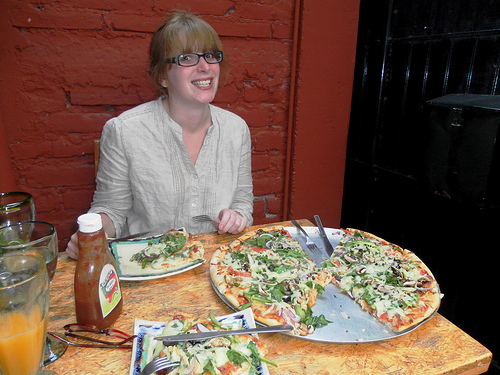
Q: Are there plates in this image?
A: Yes, there is a plate.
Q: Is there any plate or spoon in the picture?
A: Yes, there is a plate.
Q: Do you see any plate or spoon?
A: Yes, there is a plate.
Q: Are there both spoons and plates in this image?
A: No, there is a plate but no spoons.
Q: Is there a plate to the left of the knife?
A: Yes, there is a plate to the left of the knife.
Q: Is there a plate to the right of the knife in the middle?
A: No, the plate is to the left of the knife.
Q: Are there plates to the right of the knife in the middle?
A: No, the plate is to the left of the knife.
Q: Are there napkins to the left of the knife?
A: No, there is a plate to the left of the knife.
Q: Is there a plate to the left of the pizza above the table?
A: Yes, there is a plate to the left of the pizza.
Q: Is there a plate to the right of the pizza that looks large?
A: No, the plate is to the left of the pizza.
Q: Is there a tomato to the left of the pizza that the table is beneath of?
A: No, there is a plate to the left of the pizza.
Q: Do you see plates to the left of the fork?
A: Yes, there is a plate to the left of the fork.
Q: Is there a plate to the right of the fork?
A: No, the plate is to the left of the fork.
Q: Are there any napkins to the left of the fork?
A: No, there is a plate to the left of the fork.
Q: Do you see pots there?
A: No, there are no pots.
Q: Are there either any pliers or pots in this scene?
A: No, there are no pots or pliers.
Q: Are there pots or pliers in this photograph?
A: No, there are no pots or pliers.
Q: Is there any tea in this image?
A: No, there is no tea.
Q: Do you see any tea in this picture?
A: No, there is no tea.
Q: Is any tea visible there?
A: No, there is no tea.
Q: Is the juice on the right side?
A: No, the juice is on the left of the image.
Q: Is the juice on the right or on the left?
A: The juice is on the left of the image.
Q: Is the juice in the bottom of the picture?
A: Yes, the juice is in the bottom of the image.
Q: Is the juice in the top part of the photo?
A: No, the juice is in the bottom of the image.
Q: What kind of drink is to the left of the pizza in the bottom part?
A: The drink is juice.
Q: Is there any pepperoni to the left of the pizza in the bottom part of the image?
A: No, there is juice to the left of the pizza.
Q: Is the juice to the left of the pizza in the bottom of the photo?
A: Yes, the juice is to the left of the pizza.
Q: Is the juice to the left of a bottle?
A: No, the juice is to the left of the pizza.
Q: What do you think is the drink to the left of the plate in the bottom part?
A: The drink is juice.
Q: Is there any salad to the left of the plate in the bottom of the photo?
A: No, there is juice to the left of the plate.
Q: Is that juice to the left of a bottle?
A: No, the juice is to the left of a plate.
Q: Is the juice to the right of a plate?
A: No, the juice is to the left of a plate.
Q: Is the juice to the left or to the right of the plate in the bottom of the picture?
A: The juice is to the left of the plate.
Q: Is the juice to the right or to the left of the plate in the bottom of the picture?
A: The juice is to the left of the plate.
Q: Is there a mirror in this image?
A: No, there are no mirrors.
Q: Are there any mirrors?
A: No, there are no mirrors.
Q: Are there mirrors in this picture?
A: No, there are no mirrors.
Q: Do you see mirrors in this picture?
A: No, there are no mirrors.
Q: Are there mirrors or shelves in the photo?
A: No, there are no mirrors or shelves.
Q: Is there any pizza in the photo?
A: Yes, there is a pizza.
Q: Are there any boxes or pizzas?
A: Yes, there is a pizza.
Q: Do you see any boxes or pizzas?
A: Yes, there is a pizza.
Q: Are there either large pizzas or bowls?
A: Yes, there is a large pizza.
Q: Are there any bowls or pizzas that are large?
A: Yes, the pizza is large.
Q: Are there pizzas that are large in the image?
A: Yes, there is a large pizza.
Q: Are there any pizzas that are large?
A: Yes, there is a pizza that is large.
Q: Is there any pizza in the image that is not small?
A: Yes, there is a large pizza.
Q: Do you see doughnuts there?
A: No, there are no doughnuts.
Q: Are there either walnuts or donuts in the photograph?
A: No, there are no donuts or walnuts.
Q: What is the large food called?
A: The food is a pizza.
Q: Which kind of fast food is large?
A: The fast food is a pizza.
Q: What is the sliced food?
A: The food is a pizza.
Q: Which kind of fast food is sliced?
A: The fast food is a pizza.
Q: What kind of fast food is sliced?
A: The fast food is a pizza.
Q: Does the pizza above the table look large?
A: Yes, the pizza is large.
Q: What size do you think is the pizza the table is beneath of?
A: The pizza is large.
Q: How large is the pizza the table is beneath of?
A: The pizza is large.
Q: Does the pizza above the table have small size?
A: No, the pizza is large.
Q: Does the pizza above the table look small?
A: No, the pizza is large.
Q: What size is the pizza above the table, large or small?
A: The pizza is large.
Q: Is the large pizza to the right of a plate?
A: Yes, the pizza is to the right of a plate.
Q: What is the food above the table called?
A: The food is a pizza.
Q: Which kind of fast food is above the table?
A: The food is a pizza.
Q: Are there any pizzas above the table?
A: Yes, there is a pizza above the table.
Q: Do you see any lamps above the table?
A: No, there is a pizza above the table.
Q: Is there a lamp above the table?
A: No, there is a pizza above the table.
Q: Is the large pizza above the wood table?
A: Yes, the pizza is above the table.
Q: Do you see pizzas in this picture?
A: Yes, there is a pizza.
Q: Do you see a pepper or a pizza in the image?
A: Yes, there is a pizza.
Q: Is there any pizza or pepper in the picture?
A: Yes, there is a pizza.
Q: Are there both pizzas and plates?
A: Yes, there are both a pizza and a plate.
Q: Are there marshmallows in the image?
A: No, there are no marshmallows.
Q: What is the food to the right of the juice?
A: The food is a pizza.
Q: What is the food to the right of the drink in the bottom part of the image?
A: The food is a pizza.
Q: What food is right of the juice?
A: The food is a pizza.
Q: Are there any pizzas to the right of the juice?
A: Yes, there is a pizza to the right of the juice.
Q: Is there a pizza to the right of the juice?
A: Yes, there is a pizza to the right of the juice.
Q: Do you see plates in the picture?
A: Yes, there is a plate.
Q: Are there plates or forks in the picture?
A: Yes, there is a plate.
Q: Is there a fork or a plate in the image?
A: Yes, there is a plate.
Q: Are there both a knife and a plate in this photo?
A: Yes, there are both a plate and a knife.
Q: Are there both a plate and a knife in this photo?
A: Yes, there are both a plate and a knife.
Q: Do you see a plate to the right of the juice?
A: Yes, there is a plate to the right of the juice.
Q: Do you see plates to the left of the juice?
A: No, the plate is to the right of the juice.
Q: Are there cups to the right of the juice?
A: No, there is a plate to the right of the juice.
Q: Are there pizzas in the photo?
A: Yes, there is a pizza.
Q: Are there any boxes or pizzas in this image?
A: Yes, there is a pizza.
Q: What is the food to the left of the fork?
A: The food is a pizza.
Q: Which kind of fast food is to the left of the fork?
A: The food is a pizza.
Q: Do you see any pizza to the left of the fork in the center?
A: Yes, there is a pizza to the left of the fork.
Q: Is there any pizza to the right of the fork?
A: No, the pizza is to the left of the fork.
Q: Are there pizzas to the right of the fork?
A: No, the pizza is to the left of the fork.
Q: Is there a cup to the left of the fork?
A: No, there is a pizza to the left of the fork.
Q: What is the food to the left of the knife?
A: The food is a pizza.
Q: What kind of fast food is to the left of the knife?
A: The food is a pizza.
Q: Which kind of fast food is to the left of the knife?
A: The food is a pizza.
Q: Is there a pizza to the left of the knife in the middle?
A: Yes, there is a pizza to the left of the knife.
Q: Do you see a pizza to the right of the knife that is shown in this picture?
A: No, the pizza is to the left of the knife.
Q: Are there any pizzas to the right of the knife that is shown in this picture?
A: No, the pizza is to the left of the knife.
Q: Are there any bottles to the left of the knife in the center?
A: No, there is a pizza to the left of the knife.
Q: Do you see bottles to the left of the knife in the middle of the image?
A: No, there is a pizza to the left of the knife.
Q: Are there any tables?
A: Yes, there is a table.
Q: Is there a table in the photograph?
A: Yes, there is a table.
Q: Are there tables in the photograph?
A: Yes, there is a table.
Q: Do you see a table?
A: Yes, there is a table.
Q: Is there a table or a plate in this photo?
A: Yes, there is a table.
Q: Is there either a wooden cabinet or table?
A: Yes, there is a wood table.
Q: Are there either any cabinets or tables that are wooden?
A: Yes, the table is wooden.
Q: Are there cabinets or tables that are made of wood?
A: Yes, the table is made of wood.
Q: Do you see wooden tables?
A: Yes, there is a wood table.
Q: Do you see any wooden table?
A: Yes, there is a wood table.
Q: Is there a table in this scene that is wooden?
A: Yes, there is a table that is wooden.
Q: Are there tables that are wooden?
A: Yes, there is a table that is wooden.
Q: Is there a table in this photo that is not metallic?
A: Yes, there is a wooden table.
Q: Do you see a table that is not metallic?
A: Yes, there is a wooden table.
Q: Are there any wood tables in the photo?
A: Yes, there is a table that is made of wood.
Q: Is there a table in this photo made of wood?
A: Yes, there is a table that is made of wood.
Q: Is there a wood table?
A: Yes, there is a table that is made of wood.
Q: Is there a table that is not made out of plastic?
A: Yes, there is a table that is made of wood.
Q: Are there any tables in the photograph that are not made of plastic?
A: Yes, there is a table that is made of wood.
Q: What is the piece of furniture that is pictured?
A: The piece of furniture is a table.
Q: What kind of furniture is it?
A: The piece of furniture is a table.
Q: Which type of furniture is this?
A: This is a table.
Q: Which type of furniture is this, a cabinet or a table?
A: This is a table.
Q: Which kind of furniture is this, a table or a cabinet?
A: This is a table.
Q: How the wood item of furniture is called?
A: The piece of furniture is a table.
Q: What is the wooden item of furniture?
A: The piece of furniture is a table.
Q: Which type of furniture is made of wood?
A: The furniture is a table.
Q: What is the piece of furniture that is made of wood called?
A: The piece of furniture is a table.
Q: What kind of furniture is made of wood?
A: The furniture is a table.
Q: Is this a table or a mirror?
A: This is a table.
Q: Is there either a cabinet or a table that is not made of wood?
A: No, there is a table but it is made of wood.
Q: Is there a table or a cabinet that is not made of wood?
A: No, there is a table but it is made of wood.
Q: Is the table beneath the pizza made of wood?
A: Yes, the table is made of wood.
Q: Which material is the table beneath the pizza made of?
A: The table is made of wood.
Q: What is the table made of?
A: The table is made of wood.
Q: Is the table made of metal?
A: No, the table is made of wood.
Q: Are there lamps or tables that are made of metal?
A: No, there is a table but it is made of wood.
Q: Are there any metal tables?
A: No, there is a table but it is made of wood.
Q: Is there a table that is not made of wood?
A: No, there is a table but it is made of wood.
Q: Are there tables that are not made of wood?
A: No, there is a table but it is made of wood.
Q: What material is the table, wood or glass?
A: The table is made of wood.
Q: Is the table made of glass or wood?
A: The table is made of wood.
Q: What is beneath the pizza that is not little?
A: The table is beneath the pizza.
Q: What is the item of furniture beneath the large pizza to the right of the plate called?
A: The piece of furniture is a table.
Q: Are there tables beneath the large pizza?
A: Yes, there is a table beneath the pizza.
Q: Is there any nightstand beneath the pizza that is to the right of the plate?
A: No, there is a table beneath the pizza.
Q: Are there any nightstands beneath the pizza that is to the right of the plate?
A: No, there is a table beneath the pizza.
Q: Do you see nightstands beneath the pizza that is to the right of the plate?
A: No, there is a table beneath the pizza.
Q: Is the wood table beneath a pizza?
A: Yes, the table is beneath a pizza.